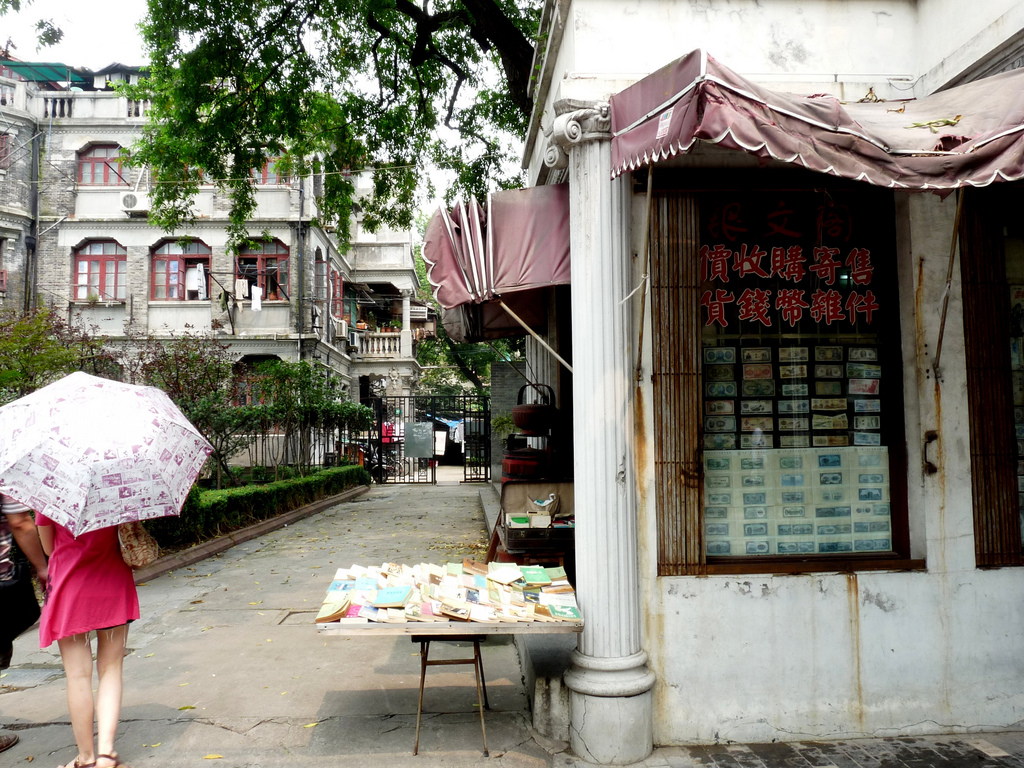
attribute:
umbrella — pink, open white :
[1, 354, 228, 564]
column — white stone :
[560, 154, 669, 753]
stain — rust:
[910, 288, 952, 513]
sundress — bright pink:
[33, 525, 144, 649]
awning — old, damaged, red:
[605, 40, 986, 207]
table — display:
[315, 541, 570, 732]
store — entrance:
[345, 18, 983, 744]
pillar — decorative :
[540, 122, 659, 749]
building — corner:
[373, 24, 983, 744]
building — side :
[0, 33, 420, 414]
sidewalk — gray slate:
[240, 467, 429, 751]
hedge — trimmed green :
[213, 472, 265, 520]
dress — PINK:
[4, 482, 162, 649]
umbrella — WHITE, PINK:
[4, 370, 233, 537]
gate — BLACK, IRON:
[374, 387, 504, 487]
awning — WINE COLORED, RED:
[598, 44, 1022, 209]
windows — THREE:
[63, 230, 299, 315]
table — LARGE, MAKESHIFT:
[311, 552, 599, 756]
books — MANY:
[309, 556, 590, 643]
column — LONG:
[544, 93, 678, 759]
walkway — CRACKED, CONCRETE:
[4, 476, 566, 764]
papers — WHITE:
[309, 562, 575, 642]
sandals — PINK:
[56, 748, 128, 764]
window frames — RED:
[69, 245, 136, 310]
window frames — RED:
[62, 135, 138, 203]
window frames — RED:
[229, 249, 299, 304]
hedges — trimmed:
[156, 462, 368, 558]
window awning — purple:
[599, 49, 1016, 190]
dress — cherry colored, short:
[37, 510, 133, 651]